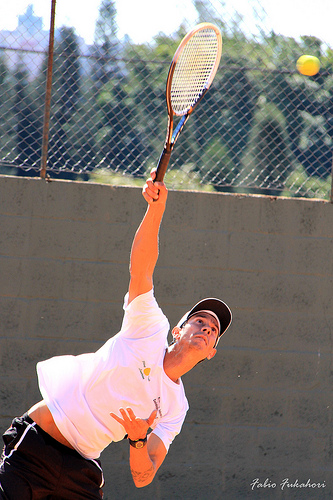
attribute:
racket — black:
[128, 16, 227, 191]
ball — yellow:
[297, 52, 322, 76]